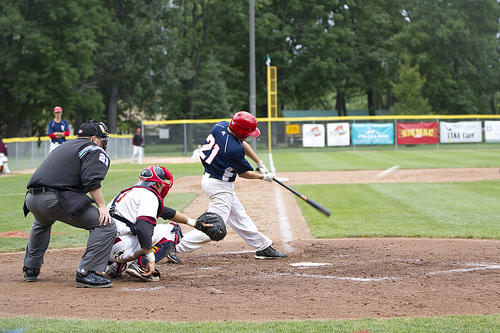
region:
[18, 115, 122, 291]
the umpire is crouching to observe the pitch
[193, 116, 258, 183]
the batter's team wears blue jerseys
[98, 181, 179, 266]
the catcher's team is wearing white jerseys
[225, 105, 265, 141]
the batter is wearing a batting helmet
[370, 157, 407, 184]
the batter has just hit the ball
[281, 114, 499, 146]
sponsor advertising along the back fence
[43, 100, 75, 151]
the third base coach watches from the sidelines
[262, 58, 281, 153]
this yellow pole helps determine if a ball stays fair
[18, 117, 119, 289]
the umpire traditionally wears black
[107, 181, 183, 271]
the home team traditionally wears white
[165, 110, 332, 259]
a kid swinging a baseball bat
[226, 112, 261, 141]
a red hard hat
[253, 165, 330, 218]
a black baseball bat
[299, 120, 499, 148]
advertisement on a fence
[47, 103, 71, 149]
man standing in a baseball field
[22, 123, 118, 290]
umpire crouching behind a catcher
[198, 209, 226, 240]
a black catcher's mitt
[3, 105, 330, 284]
people on a baseball field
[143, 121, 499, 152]
a metal fence on a baseball field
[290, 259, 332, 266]
a white home plate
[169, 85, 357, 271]
batter hit the ball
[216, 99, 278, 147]
the helmet is red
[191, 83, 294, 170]
the helmet is red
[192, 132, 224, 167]
The number 21 on the boys jersey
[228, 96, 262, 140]
The mans red baseball hat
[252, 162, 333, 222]
The boys bat the is being swung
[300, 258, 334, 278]
The home base plate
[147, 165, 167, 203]
The umpires helmet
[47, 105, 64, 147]
A boy standing in the far left feild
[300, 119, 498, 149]
The banners on the fence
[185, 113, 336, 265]
A boy swinging a bat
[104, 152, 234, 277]
A boy with a catchers mitt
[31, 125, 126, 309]
An umpire in uniform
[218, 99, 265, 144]
A person is wearing a red helmet.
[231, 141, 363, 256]
A person is holding a bat.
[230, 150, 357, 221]
A person is swinging a bat.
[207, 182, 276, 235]
A peson is wearing white pants.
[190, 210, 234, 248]
A person is holding a catchers mit.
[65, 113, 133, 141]
A person is wearing a black hat.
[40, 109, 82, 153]
A person has his arms cross.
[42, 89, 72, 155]
A person is standing in a baseball field.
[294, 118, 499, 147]
Banners are displayed on a fence.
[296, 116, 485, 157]
A fence is displaying banners.